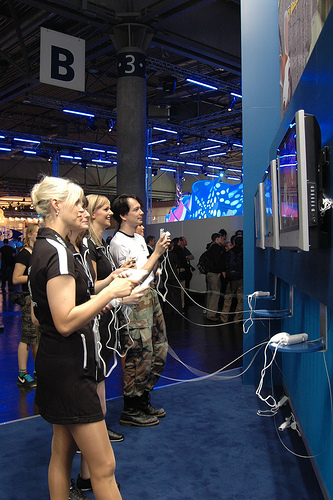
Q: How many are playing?
A: 4.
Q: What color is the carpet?
A: Blue.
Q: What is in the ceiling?
A: Lights.